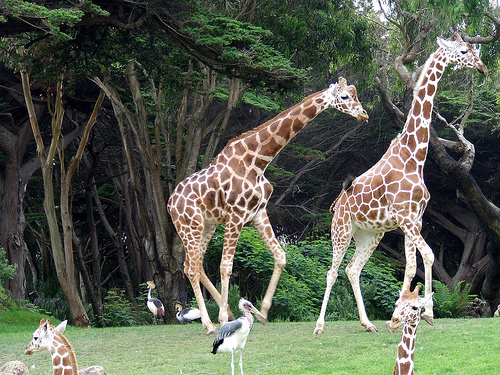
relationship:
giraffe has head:
[196, 128, 301, 244] [319, 76, 369, 124]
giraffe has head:
[382, 270, 431, 373] [380, 277, 438, 372]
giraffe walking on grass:
[315, 23, 486, 332] [305, 330, 370, 367]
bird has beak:
[211, 295, 266, 371] [250, 305, 266, 322]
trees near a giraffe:
[8, 4, 165, 324] [163, 70, 370, 330]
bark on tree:
[108, 82, 180, 294] [14, 17, 181, 317]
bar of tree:
[23, 76, 108, 335] [11, 1, 188, 373]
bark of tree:
[453, 165, 468, 181] [361, 0, 498, 318]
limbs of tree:
[21, 73, 123, 340] [0, 14, 289, 345]